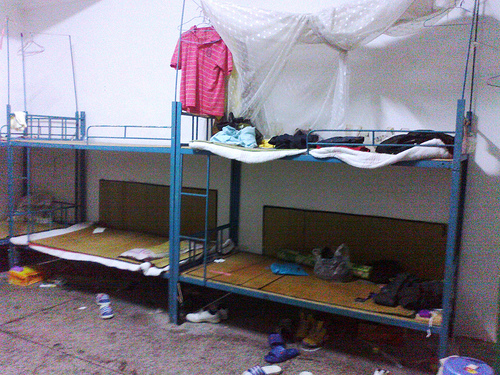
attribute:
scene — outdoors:
[365, 357, 434, 371]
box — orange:
[8, 242, 40, 296]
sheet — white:
[204, 5, 481, 126]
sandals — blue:
[264, 331, 307, 361]